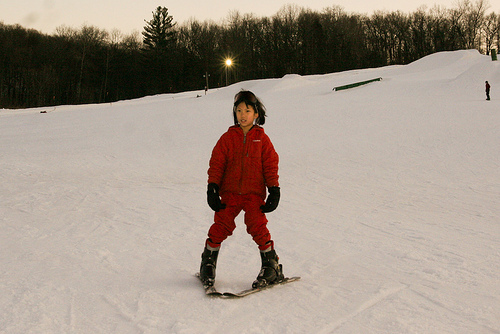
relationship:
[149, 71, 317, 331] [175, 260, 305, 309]
child on skis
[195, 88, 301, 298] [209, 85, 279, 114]
child has hair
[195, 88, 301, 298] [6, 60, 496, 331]
child standing on snow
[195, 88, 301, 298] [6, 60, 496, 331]
child in snow